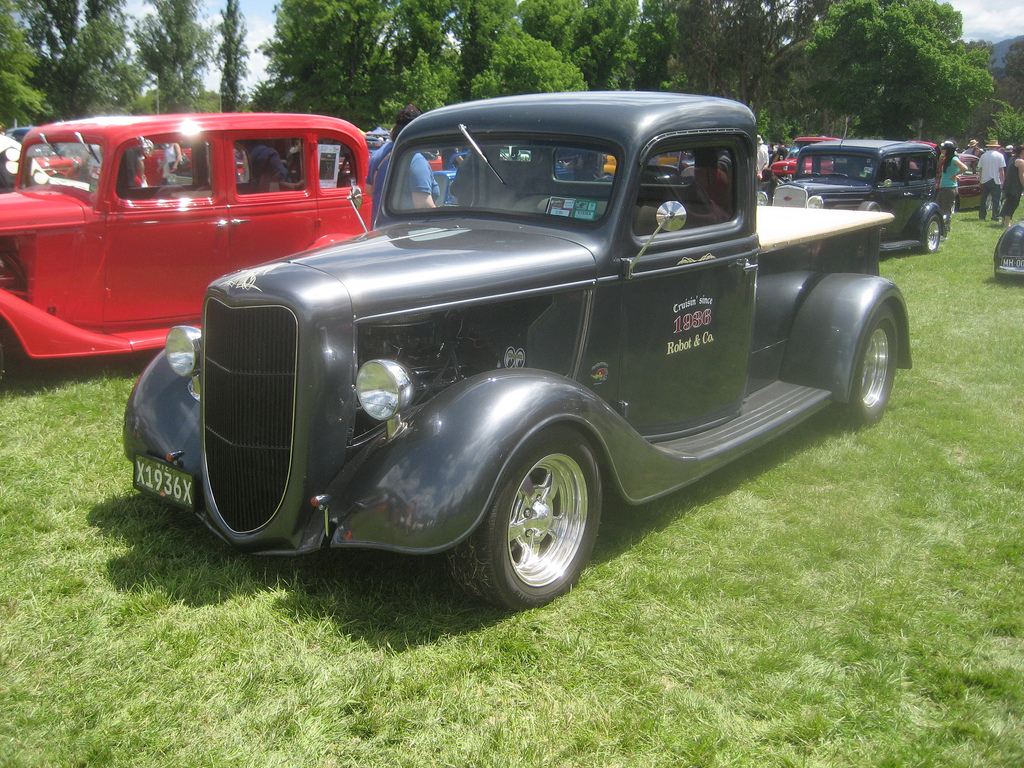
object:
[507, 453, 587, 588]
rim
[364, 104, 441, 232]
person shirt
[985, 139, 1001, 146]
man hat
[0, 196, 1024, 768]
grass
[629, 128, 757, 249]
open window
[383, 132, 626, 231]
glass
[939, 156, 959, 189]
blue shirt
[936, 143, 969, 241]
person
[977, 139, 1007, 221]
man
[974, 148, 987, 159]
shirt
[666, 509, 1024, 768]
ground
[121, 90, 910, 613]
black truck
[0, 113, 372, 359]
red truck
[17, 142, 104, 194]
windshield